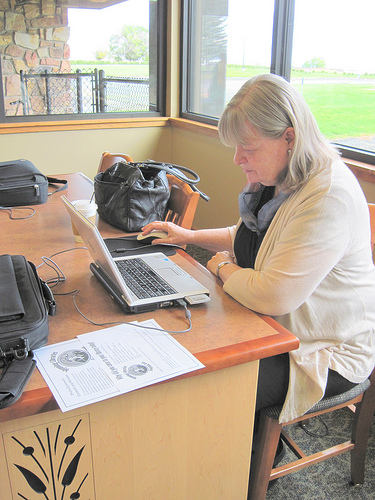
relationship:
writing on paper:
[49, 345, 89, 371] [22, 318, 204, 410]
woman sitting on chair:
[139, 73, 374, 405] [249, 203, 373, 496]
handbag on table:
[84, 149, 212, 234] [178, 308, 276, 359]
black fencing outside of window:
[18, 68, 153, 114] [0, 1, 151, 116]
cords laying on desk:
[37, 243, 191, 333] [1, 226, 110, 372]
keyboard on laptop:
[112, 250, 199, 318] [61, 198, 208, 308]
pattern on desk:
[3, 411, 97, 498] [1, 169, 304, 496]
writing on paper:
[61, 364, 112, 398] [22, 318, 204, 410]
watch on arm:
[216, 260, 234, 278] [205, 195, 349, 315]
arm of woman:
[205, 195, 349, 315] [140, 72, 373, 466]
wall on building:
[167, 124, 372, 266] [1, 1, 373, 499]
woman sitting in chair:
[139, 73, 374, 405] [273, 380, 368, 493]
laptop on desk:
[34, 206, 250, 332] [1, 169, 304, 496]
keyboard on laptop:
[52, 188, 227, 327] [45, 179, 214, 329]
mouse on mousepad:
[135, 227, 174, 247] [101, 230, 177, 255]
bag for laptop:
[0, 249, 61, 354] [58, 190, 218, 317]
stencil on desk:
[10, 418, 88, 499] [1, 169, 304, 496]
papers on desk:
[28, 316, 208, 412] [0, 200, 87, 257]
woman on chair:
[139, 73, 374, 405] [237, 188, 374, 498]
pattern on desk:
[3, 411, 97, 498] [12, 159, 303, 386]